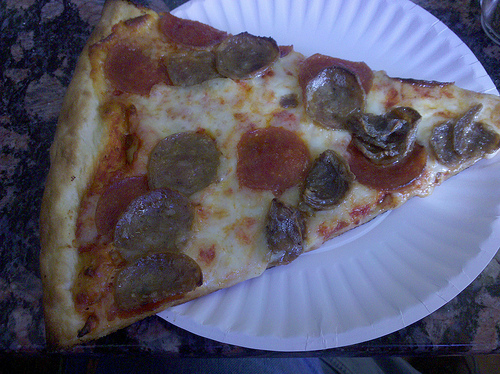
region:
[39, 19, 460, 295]
slice of pizza on plate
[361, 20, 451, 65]
white paper plate ridges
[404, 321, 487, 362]
edge of table under plate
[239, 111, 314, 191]
pepperoni on pizza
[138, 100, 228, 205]
slice of sausage on pizza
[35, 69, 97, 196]
cooked edge of crust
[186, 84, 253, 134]
melted cheese on pizza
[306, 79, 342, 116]
shiny grease on sausage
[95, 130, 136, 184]
dried tomato sauce on pizza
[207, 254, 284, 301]
melted cheese on edge of pizza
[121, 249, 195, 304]
a pizza topping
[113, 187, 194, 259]
a pizza topping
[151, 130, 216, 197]
a pizza topping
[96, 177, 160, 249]
a pizza topping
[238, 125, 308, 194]
a pizza topping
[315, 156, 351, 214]
a pizza topping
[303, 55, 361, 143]
a pizza topping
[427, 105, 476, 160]
a pizza topping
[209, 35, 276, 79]
a pizza topping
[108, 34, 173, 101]
a pizza topping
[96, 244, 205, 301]
some pizza toppings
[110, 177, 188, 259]
some pizza toppings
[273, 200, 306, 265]
some pizza toppings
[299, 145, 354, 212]
some pizza toppings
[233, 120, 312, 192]
some pizza toppings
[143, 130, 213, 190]
some pizza toppings on pizza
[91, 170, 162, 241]
some pizza toppings on pizza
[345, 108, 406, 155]
some pizza toppings on pizza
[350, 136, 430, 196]
some pizza toppings on pizza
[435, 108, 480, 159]
some pizza toppings on pizza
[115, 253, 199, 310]
a slice of pizza topping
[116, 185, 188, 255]
a slice of pizza topping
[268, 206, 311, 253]
a slice of pizza topping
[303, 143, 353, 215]
a slice of pizza topping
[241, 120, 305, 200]
a slice of pizza topping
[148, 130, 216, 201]
a slice of pizza topping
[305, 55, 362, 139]
a slice of pizza topping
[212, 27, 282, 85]
a slice of pizza topping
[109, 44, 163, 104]
a slice of pizza topping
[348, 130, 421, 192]
a slice of pizza topping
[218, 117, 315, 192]
Pepperoni on a pizza.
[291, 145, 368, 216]
Mushroom on the pizza.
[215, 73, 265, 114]
Grease on the cheese.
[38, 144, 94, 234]
The crust is tan.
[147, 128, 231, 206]
A grey circular meat.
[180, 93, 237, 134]
The cheese is white.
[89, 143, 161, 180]
Sauce on the pizza.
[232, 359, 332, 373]
The jeans are blue.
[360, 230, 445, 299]
The paper plate is white.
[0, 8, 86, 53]
The table is marble.